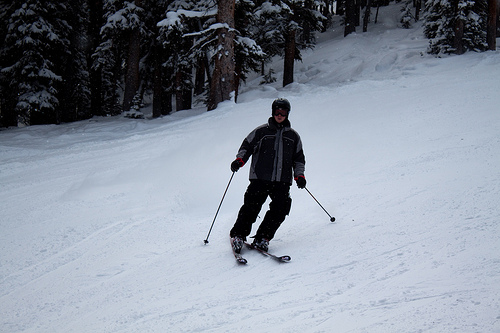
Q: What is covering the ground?
A: Snow.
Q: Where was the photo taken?
A: Ski slope.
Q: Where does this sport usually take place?
A: Mountains.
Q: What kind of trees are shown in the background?
A: Pine trees.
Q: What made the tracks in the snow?
A: Skis.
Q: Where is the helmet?
A: On skier.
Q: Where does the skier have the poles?
A: Hands.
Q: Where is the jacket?
A: On skier.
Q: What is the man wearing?
A: Grey and blue jacket.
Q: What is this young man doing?
A: Skiing.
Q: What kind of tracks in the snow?
A: Ski tracks.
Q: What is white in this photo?
A: Snow on the ground.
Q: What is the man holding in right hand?
A: Ski pole.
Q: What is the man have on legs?
A: Black pants.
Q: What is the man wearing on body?
A: A snow jacket.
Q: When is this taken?
A: Daytime.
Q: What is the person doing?
A: Skiing.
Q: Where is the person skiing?
A: A ski slope.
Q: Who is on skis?
A: The skier.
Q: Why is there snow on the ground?
A: It is winter.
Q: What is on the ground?
A: Snow.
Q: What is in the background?
A: Trees.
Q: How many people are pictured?
A: One.